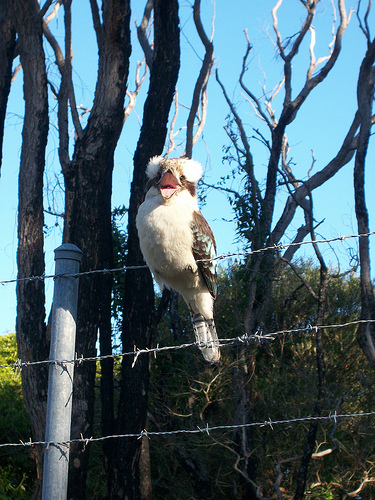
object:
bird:
[136, 155, 224, 367]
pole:
[37, 242, 85, 499]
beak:
[154, 167, 183, 201]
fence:
[0, 228, 375, 448]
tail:
[179, 290, 222, 365]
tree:
[1, 0, 133, 499]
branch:
[288, 0, 349, 116]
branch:
[238, 23, 278, 133]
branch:
[305, 146, 318, 182]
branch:
[353, 1, 372, 50]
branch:
[55, 0, 74, 175]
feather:
[149, 269, 165, 313]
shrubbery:
[0, 259, 375, 499]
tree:
[212, 0, 360, 459]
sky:
[1, 0, 375, 337]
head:
[143, 154, 205, 204]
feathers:
[178, 159, 205, 186]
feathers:
[143, 154, 165, 183]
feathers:
[190, 210, 219, 302]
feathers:
[190, 303, 222, 367]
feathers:
[133, 187, 197, 286]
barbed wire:
[1, 319, 374, 373]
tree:
[203, 67, 262, 269]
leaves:
[223, 190, 259, 243]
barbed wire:
[1, 228, 374, 284]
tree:
[1, 331, 54, 499]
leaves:
[1, 334, 35, 498]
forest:
[1, 2, 374, 499]